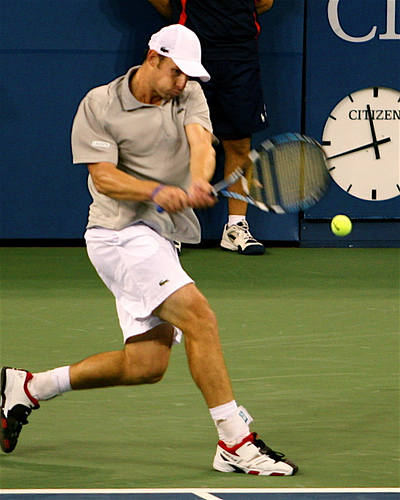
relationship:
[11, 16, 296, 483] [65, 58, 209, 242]
man wearing a shirt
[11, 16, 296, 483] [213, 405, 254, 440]
man wearing an ankle brace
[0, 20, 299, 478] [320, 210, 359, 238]
man hitting a ball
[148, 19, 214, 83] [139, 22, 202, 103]
hat on a player's head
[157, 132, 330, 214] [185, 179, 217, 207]
racket in a hand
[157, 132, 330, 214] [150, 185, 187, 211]
racket in a hand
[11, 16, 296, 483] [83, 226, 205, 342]
man wearing white shorts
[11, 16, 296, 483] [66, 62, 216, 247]
man wearing gray shirt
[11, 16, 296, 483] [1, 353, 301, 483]
man wearing shoes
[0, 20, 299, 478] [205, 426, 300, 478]
man wearing shoes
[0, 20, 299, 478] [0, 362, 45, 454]
man wearing shoes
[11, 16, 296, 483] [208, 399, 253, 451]
man wearing socks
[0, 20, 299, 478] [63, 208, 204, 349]
man wearing shorts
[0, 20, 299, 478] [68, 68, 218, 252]
man wearing shirt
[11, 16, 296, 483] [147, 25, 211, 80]
man wearing hat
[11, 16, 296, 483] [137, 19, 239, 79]
man wearing hat